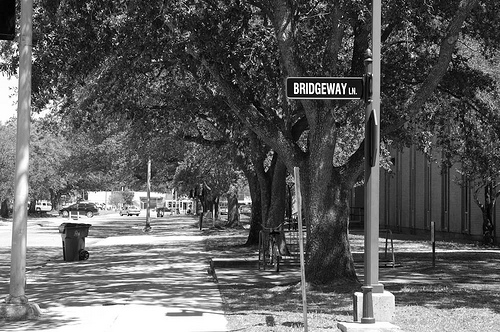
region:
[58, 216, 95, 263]
trash can at the curb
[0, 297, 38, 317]
base for the street light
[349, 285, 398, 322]
a block for the post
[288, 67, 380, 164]
a traffic sign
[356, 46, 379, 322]
a pole for the street sign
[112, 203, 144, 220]
a car on the road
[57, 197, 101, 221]
A car parked in the driveway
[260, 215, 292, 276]
a bike standing up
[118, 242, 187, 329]
shadows on the sidewalk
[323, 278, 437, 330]
posts on the grass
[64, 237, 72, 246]
the trash can is black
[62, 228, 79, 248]
the trash can is black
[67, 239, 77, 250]
the trash can is black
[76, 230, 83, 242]
the trash can is black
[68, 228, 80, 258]
the trash can is black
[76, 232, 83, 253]
the trash can is black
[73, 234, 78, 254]
the trash can is black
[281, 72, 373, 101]
a street sign on the post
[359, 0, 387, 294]
a metal sign post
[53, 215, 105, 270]
a trash can on the sidewalk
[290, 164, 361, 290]
the trunk of a tree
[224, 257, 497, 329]
a grassy yard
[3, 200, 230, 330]
a cement sidewalk next to the street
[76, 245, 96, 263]
the wheel of a trash can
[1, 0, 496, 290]
a large leafy tree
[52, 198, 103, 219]
a car in a driveway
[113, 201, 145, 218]
a car on the street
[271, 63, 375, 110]
sign on the pole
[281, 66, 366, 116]
sign that says "Bridgeway"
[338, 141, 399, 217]
pole holding a sign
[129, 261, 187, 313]
cement next to pole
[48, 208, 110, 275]
trash can on street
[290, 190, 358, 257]
tree trunk on ground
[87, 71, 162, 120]
leaves on the tree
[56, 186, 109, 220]
parked car in the driveway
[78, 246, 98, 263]
wheel on the trash can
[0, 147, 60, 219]
pole on the street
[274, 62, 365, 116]
sign above the street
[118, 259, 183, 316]
cement below the sign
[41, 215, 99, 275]
trash can next to street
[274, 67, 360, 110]
the word "Bridgeway" on sign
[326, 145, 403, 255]
pole holding the sign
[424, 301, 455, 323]
grass below the sign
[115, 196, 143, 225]
car on the street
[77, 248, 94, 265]
wheel of the trash can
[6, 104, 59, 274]
pole next to street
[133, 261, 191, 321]
shadow on sidewalk